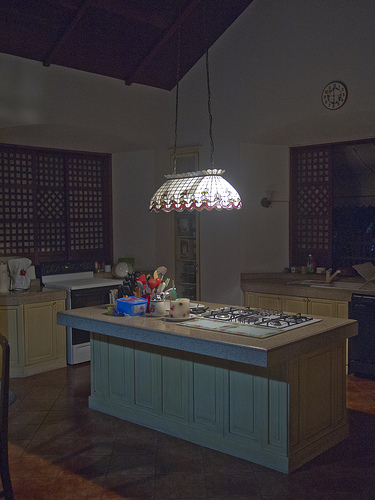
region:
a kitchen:
[11, 27, 371, 498]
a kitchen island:
[88, 283, 347, 451]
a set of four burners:
[212, 301, 314, 337]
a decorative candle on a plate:
[166, 297, 198, 322]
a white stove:
[49, 257, 115, 343]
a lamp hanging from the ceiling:
[152, 1, 242, 228]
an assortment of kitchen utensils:
[122, 266, 167, 296]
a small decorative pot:
[147, 296, 166, 317]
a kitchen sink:
[294, 265, 367, 298]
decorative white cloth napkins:
[6, 256, 36, 291]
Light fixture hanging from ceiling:
[144, 42, 250, 224]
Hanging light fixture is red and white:
[150, 150, 254, 220]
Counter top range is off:
[204, 302, 326, 333]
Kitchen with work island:
[60, 269, 364, 476]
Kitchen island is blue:
[49, 310, 306, 471]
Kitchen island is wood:
[58, 309, 295, 478]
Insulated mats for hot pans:
[183, 312, 281, 344]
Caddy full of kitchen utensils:
[140, 268, 169, 315]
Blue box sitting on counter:
[114, 293, 148, 319]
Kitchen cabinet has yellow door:
[9, 286, 72, 377]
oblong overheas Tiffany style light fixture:
[138, 158, 245, 215]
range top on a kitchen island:
[203, 291, 365, 386]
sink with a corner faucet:
[311, 266, 365, 297]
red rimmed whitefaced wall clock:
[317, 75, 349, 113]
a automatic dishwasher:
[41, 249, 111, 378]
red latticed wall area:
[5, 143, 119, 266]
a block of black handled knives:
[112, 252, 140, 302]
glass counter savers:
[176, 305, 283, 343]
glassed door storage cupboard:
[165, 146, 207, 300]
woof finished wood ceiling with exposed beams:
[2, 0, 249, 110]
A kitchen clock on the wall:
[293, 74, 353, 123]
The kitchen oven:
[51, 255, 120, 331]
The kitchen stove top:
[206, 289, 306, 349]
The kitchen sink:
[286, 264, 373, 307]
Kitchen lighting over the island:
[133, 137, 244, 219]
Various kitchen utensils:
[107, 262, 182, 311]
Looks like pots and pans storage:
[156, 227, 224, 284]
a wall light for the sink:
[260, 176, 285, 216]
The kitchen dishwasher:
[344, 290, 374, 323]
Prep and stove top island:
[77, 275, 358, 456]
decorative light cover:
[144, 165, 248, 216]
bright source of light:
[138, 166, 264, 217]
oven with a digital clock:
[38, 252, 130, 378]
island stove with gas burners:
[172, 298, 325, 345]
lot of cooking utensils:
[114, 261, 178, 321]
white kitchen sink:
[286, 262, 366, 301]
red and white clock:
[314, 73, 359, 115]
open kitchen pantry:
[162, 145, 212, 321]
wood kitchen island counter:
[54, 279, 359, 476]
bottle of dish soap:
[295, 241, 327, 281]